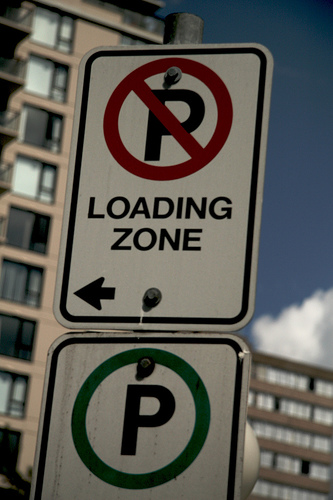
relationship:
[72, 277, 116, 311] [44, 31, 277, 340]
arrow on signs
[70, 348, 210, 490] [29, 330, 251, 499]
parking symbol on sign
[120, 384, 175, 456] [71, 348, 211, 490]
p in circle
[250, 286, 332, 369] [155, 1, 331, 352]
cloud in sky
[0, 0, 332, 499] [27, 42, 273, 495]
building behind signs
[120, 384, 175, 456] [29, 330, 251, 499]
p on sign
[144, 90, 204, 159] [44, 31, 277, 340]
p on signs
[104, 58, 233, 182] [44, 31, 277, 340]
circle on signs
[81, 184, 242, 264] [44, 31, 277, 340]
letters on signs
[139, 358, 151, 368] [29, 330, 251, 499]
bolt on sign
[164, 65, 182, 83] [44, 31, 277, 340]
bolt on signs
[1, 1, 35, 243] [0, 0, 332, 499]
balconies on building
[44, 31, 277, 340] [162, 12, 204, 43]
signs on pole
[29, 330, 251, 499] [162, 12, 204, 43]
sign on pole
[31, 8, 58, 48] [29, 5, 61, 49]
curtain in window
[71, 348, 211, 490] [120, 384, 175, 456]
circle around p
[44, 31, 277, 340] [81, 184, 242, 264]
signs for letters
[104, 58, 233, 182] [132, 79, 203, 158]
circle has a slash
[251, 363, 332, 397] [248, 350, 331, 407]
windows on top floor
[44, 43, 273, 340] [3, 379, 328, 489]
signs on street